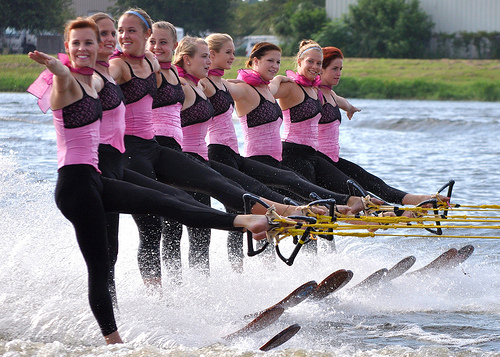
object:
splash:
[268, 295, 340, 350]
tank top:
[47, 72, 108, 176]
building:
[0, 24, 66, 52]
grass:
[0, 53, 500, 101]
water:
[0, 91, 500, 356]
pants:
[54, 163, 242, 335]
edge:
[327, 267, 351, 283]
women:
[168, 35, 356, 273]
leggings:
[52, 161, 300, 347]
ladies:
[78, 10, 308, 317]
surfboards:
[379, 255, 420, 286]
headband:
[299, 45, 327, 57]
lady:
[214, 40, 339, 252]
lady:
[320, 45, 454, 211]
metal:
[262, 203, 289, 246]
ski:
[253, 321, 305, 352]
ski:
[278, 279, 317, 310]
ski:
[406, 247, 456, 279]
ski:
[308, 269, 351, 304]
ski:
[443, 242, 473, 270]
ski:
[385, 251, 423, 285]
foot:
[248, 211, 297, 235]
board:
[344, 265, 388, 293]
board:
[221, 305, 290, 339]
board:
[254, 321, 301, 354]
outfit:
[50, 73, 242, 338]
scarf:
[26, 52, 94, 117]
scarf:
[106, 47, 144, 62]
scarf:
[235, 68, 272, 89]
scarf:
[288, 69, 322, 91]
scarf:
[172, 64, 200, 86]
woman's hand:
[29, 48, 62, 71]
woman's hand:
[344, 102, 360, 119]